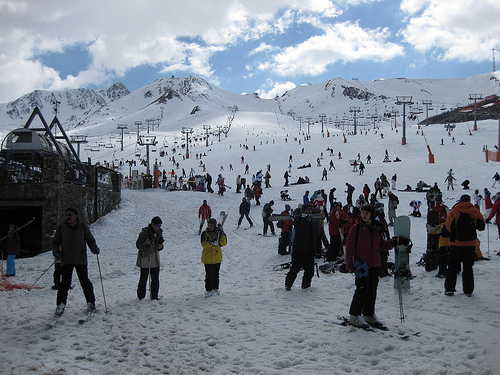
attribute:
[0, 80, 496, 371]
snow — white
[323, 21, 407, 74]
clouds — white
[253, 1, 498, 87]
sky — blue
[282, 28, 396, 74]
clouds — white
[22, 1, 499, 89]
sky — blue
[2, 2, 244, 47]
cloud — white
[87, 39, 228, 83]
cloud — white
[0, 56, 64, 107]
cloud — white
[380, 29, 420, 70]
sky — blue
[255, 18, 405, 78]
cloud — white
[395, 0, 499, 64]
cloud — white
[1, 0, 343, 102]
cloud — white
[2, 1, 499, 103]
clouds — white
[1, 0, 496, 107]
sky — blue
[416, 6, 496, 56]
clouds — white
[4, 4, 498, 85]
sky — blue